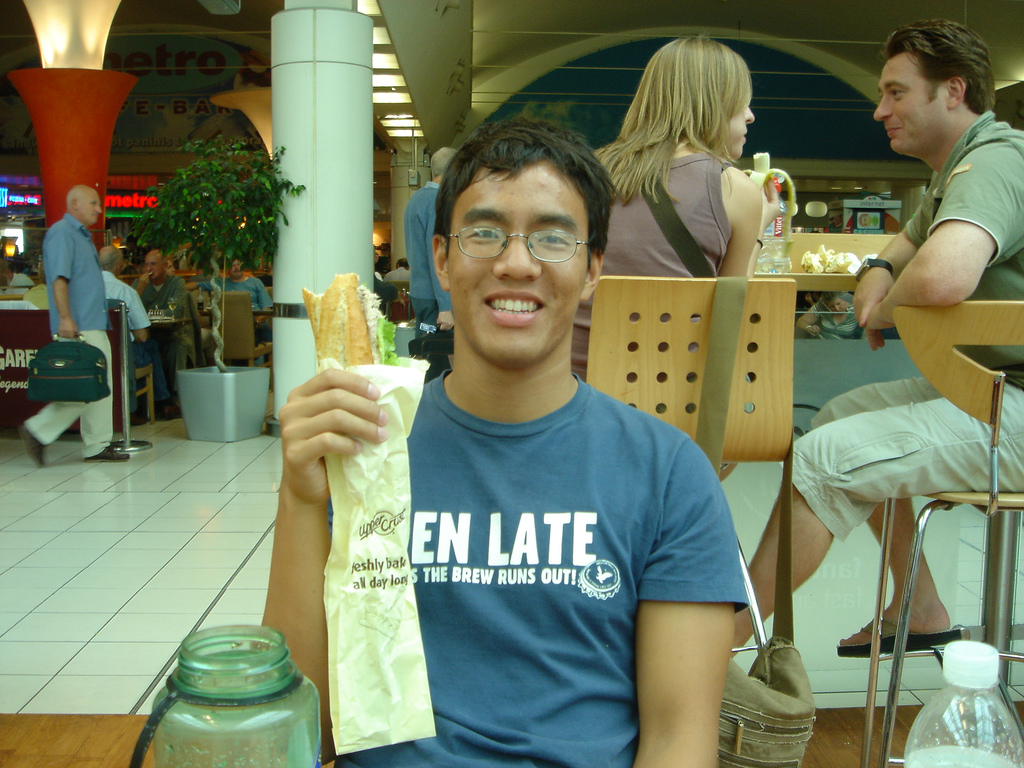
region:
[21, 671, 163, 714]
white tile on food court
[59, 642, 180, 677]
white tile on food court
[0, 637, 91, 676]
white tile on food court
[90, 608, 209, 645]
white tile on food court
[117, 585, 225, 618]
white tile on food court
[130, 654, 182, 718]
white tile on food court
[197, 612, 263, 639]
white tile on food court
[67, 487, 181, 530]
white tile on food court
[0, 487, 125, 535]
white tile on food court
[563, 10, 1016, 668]
Two people sitting on chairs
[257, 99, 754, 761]
A guy is holding up a sandwich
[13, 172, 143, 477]
A man is holding a green bag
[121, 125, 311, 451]
Small tree in a pot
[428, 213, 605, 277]
A pair of eyeglasses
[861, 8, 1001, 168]
Brown hair on man's head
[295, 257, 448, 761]
A long sandwich in a bag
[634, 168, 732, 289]
Black strap of a bag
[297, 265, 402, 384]
sandwich poking out of the wrapper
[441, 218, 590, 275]
glasses on the man's face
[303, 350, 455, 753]
paper wrapper on the sandwich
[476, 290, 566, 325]
smile on a man's face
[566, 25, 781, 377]
woman in a purple shirt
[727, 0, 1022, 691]
man in tan shorts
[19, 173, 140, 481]
man carrying a suitcase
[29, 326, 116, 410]
green colored suitcase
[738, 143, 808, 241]
banana in a woman's hand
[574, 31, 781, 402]
woman with blond hair wearing a purple shirt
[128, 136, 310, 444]
small green tree in large silver pot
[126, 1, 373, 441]
white column with silver band next to tree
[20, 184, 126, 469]
bald man with blue shirt carrying green bag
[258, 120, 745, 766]
man with blue shirt eating a sandwich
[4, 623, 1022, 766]
green glass jar sitting on top of brown table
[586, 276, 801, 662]
light brown chair with holes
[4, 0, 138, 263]
red column with yellow light on top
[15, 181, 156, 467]
silver metal pole next to man carrying green bag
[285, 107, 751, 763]
boy holding a sandwich in his hand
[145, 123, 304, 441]
indoor tree in planter in mall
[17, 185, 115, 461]
man carrying a small bag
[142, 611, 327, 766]
green glass jar beside boy's arm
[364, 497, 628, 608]
white writing on shirt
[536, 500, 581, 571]
a white capital letter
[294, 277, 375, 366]
a piece of a white bread sandwich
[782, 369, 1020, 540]
a man's beige shorts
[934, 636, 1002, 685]
a white bottle top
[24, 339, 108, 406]
a large bag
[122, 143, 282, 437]
a tall potted tree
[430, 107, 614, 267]
a man's short cut hair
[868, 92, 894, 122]
the nose of a man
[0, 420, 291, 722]
white tile floor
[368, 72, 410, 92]
a ceiling light